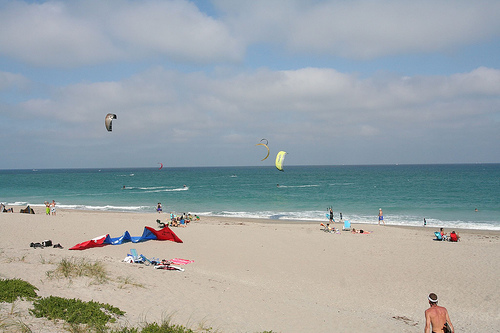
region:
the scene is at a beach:
[61, 52, 499, 322]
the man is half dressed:
[417, 292, 457, 332]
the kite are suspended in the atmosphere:
[246, 144, 327, 172]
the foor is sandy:
[236, 243, 333, 320]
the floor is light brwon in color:
[241, 238, 362, 324]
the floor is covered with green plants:
[24, 271, 183, 324]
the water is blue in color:
[373, 178, 447, 200]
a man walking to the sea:
[369, 209, 393, 229]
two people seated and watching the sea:
[431, 227, 468, 250]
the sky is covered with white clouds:
[302, 81, 437, 127]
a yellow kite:
[274, 150, 285, 173]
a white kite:
[104, 109, 115, 134]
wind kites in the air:
[93, 115, 322, 196]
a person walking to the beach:
[423, 289, 455, 329]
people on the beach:
[48, 188, 473, 260]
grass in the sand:
[18, 277, 124, 328]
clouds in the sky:
[148, 20, 475, 111]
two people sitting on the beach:
[436, 225, 458, 240]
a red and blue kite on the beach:
[68, 222, 183, 248]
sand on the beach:
[216, 230, 329, 310]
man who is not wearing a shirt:
[410, 286, 458, 332]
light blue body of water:
[0, 163, 495, 228]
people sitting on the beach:
[430, 225, 462, 248]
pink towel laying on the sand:
[166, 253, 193, 267]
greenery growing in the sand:
[0, 275, 133, 331]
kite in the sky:
[103, 109, 121, 136]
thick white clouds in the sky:
[0, 2, 499, 174]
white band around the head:
[424, 290, 447, 306]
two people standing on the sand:
[39, 201, 60, 217]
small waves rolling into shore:
[4, 193, 149, 215]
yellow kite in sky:
[265, 148, 296, 196]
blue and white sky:
[85, 1, 485, 169]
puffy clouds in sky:
[81, 7, 496, 167]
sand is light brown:
[217, 227, 424, 331]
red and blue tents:
[82, 221, 162, 258]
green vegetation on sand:
[17, 273, 132, 330]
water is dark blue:
[331, 164, 463, 212]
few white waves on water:
[111, 171, 452, 219]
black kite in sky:
[100, 111, 118, 136]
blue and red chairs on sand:
[115, 243, 222, 271]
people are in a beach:
[39, 28, 466, 329]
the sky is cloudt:
[203, 30, 358, 102]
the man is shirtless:
[395, 296, 457, 331]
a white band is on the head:
[418, 288, 443, 304]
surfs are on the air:
[41, 89, 307, 181]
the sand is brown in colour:
[224, 256, 336, 306]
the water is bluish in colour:
[340, 165, 457, 204]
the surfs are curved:
[61, 111, 128, 132]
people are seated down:
[418, 216, 476, 256]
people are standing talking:
[28, 191, 63, 216]